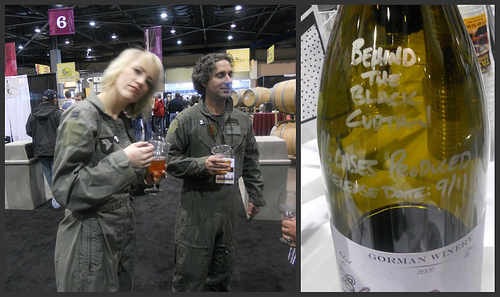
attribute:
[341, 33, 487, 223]
silver writing — silver 